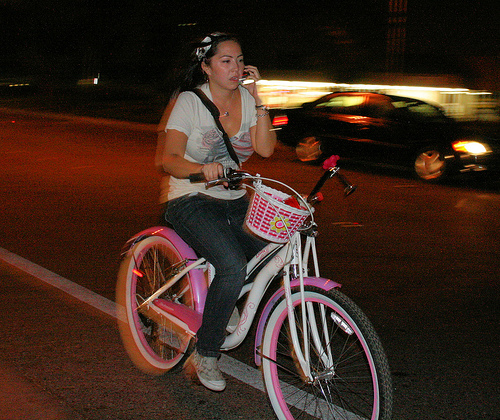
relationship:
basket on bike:
[246, 181, 315, 245] [113, 155, 395, 419]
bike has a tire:
[113, 155, 395, 419] [263, 285, 392, 419]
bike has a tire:
[113, 155, 395, 419] [115, 236, 190, 379]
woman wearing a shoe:
[157, 33, 277, 391] [192, 351, 228, 393]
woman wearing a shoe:
[157, 33, 277, 391] [227, 307, 240, 332]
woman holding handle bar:
[157, 33, 277, 391] [190, 170, 259, 187]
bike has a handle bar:
[113, 155, 395, 419] [303, 170, 355, 200]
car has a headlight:
[268, 90, 497, 185] [451, 140, 493, 157]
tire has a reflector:
[263, 285, 392, 419] [328, 307, 353, 337]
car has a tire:
[268, 90, 497, 185] [294, 134, 326, 166]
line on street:
[0, 238, 395, 419] [0, 105, 497, 419]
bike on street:
[113, 155, 395, 419] [0, 105, 497, 419]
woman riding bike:
[157, 33, 277, 391] [113, 155, 395, 419]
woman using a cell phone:
[157, 33, 277, 391] [236, 65, 249, 82]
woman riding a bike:
[157, 33, 277, 391] [113, 155, 395, 419]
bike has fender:
[113, 155, 395, 419] [255, 275, 342, 370]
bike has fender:
[113, 155, 395, 419] [122, 225, 218, 313]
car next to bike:
[268, 90, 497, 185] [113, 155, 395, 419]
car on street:
[268, 90, 497, 185] [0, 105, 497, 419]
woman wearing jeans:
[157, 33, 277, 391] [161, 194, 271, 356]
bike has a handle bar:
[113, 155, 395, 419] [190, 170, 259, 187]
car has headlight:
[268, 90, 497, 185] [451, 140, 493, 157]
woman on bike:
[157, 33, 277, 391] [113, 155, 395, 419]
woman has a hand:
[157, 33, 277, 391] [201, 162, 225, 185]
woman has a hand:
[157, 33, 277, 391] [242, 65, 259, 93]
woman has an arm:
[157, 33, 277, 391] [157, 91, 202, 178]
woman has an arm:
[157, 33, 277, 391] [251, 88, 277, 159]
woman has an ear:
[157, 33, 277, 391] [201, 59, 211, 77]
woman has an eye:
[157, 33, 277, 391] [220, 58, 232, 64]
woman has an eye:
[157, 33, 277, 391] [238, 58, 246, 64]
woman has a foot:
[157, 33, 277, 391] [191, 349, 227, 393]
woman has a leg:
[157, 33, 277, 391] [182, 216, 248, 355]